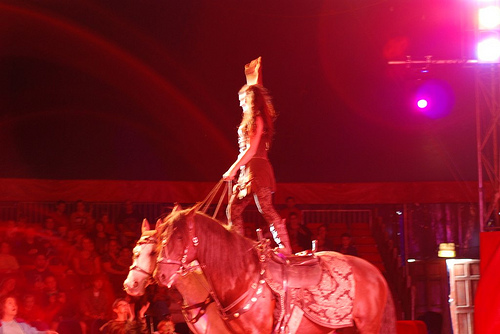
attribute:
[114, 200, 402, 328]
horses — side by side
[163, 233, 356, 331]
tack — elaborate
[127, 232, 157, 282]
bridle — fancy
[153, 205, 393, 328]
horse — brown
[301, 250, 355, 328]
blanket — metallic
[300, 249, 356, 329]
pattern — metallic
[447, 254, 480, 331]
door — brown, paneled, wooden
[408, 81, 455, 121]
halo — purple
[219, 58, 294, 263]
rider — performing, special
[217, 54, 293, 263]
woman — costumed, standing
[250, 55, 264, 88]
hand — raised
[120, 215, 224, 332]
horse — white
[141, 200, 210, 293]
head — horse's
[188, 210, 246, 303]
neck — horse's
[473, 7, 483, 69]
lights — white, glowing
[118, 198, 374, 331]
showhorse — brown, circus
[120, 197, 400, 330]
showhorse — white, circus